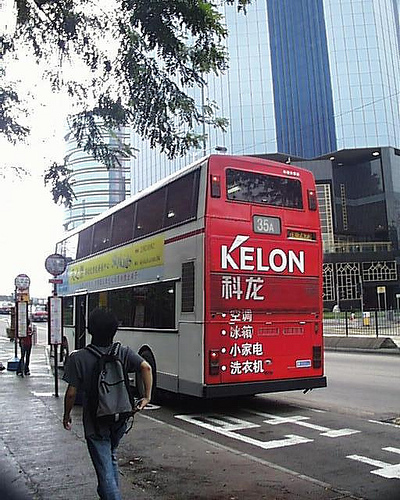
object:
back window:
[223, 164, 304, 212]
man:
[60, 303, 152, 499]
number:
[254, 218, 265, 235]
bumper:
[202, 374, 327, 402]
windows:
[339, 97, 351, 116]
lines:
[222, 430, 266, 451]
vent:
[181, 261, 194, 313]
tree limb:
[34, 1, 61, 32]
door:
[72, 294, 86, 349]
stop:
[43, 251, 68, 402]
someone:
[15, 317, 34, 380]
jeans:
[82, 363, 127, 420]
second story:
[62, 205, 122, 221]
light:
[210, 347, 220, 361]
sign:
[15, 299, 27, 339]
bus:
[43, 153, 327, 404]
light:
[165, 209, 178, 220]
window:
[162, 165, 201, 229]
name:
[220, 233, 306, 274]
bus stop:
[0, 283, 329, 499]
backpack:
[83, 343, 135, 430]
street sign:
[171, 410, 314, 451]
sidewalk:
[0, 306, 351, 499]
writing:
[227, 358, 242, 374]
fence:
[374, 306, 398, 338]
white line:
[317, 425, 362, 441]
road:
[0, 314, 399, 499]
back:
[202, 152, 327, 396]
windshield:
[221, 167, 307, 213]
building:
[128, 0, 399, 199]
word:
[218, 232, 307, 276]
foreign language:
[218, 271, 244, 303]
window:
[58, 283, 179, 335]